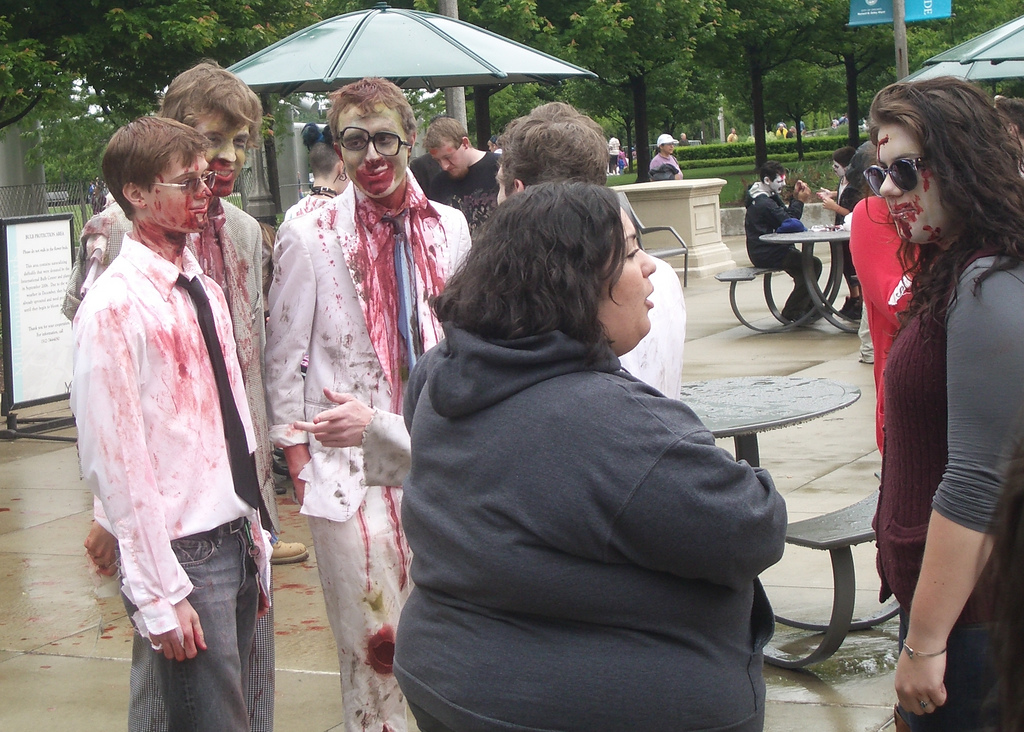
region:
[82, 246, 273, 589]
man wearing a white shirt and black tie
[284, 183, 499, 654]
man wearing a white suit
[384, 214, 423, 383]
man wearing a blue tie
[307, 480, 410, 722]
man wearing white pants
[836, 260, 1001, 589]
woman wearing a red sweater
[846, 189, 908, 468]
person wearing a red jacket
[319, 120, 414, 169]
black uneven glasses on his face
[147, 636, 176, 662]
a ring on his pinky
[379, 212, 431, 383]
a blue neck tie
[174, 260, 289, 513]
a long black neck tie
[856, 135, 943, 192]
sunglasses on her face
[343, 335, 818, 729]
a large gray hoodie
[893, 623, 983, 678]
a silver bracelet on her wrist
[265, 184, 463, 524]
a white suit jacket with red on it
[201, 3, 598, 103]
a green metal umbrella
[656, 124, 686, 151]
a white hat on the head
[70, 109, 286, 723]
person dressed like a zombie in park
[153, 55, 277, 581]
person dressed like a zombie in park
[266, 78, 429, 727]
person dressed like a zombie in park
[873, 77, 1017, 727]
person dressed like a zombie in park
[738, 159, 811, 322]
person dressed like a zombie in park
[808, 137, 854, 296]
person dressed like a zombie in park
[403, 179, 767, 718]
person dressed like a zombie in park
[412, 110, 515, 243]
person dressed like a zombie in park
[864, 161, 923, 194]
dark black sunglasses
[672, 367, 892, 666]
an outdoor table and bench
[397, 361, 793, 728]
a woman's gray hoodie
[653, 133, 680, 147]
a white baseball cap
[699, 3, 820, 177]
a large green tree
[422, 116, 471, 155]
a man's short cut brown hair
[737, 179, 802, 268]
a man's hoodie shirt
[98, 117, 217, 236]
person has a head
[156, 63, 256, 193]
person has a head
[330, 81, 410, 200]
person has a head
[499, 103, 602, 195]
person has a head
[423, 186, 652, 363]
person has a head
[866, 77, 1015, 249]
person has a head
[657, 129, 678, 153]
person has a head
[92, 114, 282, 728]
a man dressed as a zombie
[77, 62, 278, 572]
a man dressed as a zombie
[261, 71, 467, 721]
a man dressed as a zombie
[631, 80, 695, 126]
green leaves on the tree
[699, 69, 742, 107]
green leaves on the tree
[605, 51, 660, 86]
green leaves on the tree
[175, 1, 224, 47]
green leaves on the tree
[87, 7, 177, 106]
green leaves on the tree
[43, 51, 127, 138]
green leaves on the tree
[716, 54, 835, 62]
green leaves on the tree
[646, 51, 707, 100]
green leaves on the tree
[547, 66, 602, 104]
green leaves on the tree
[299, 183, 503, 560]
red and white shirt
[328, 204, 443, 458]
boy has blue tie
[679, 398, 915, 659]
grey table behind women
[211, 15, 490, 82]
green umbrella behind boys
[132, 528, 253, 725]
boy has grey pants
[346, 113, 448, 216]
boy has black glasses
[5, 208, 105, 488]
black and white sign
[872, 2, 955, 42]
green flags on poles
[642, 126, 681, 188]
person wearing a pink shirt and white hat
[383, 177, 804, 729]
lady wearing a charcoal gray hoodie